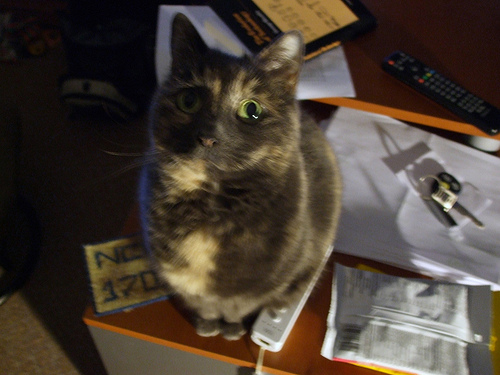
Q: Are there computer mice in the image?
A: No, there are no computer mice.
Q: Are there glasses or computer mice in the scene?
A: No, there are no computer mice or glasses.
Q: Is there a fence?
A: No, there are no fences.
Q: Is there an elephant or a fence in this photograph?
A: No, there are no fences or elephants.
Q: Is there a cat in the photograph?
A: Yes, there is a cat.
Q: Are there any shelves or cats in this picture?
A: Yes, there is a cat.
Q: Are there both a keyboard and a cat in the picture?
A: No, there is a cat but no keyboards.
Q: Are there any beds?
A: No, there are no beds.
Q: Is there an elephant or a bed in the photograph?
A: No, there are no beds or elephants.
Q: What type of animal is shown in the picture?
A: The animal is a cat.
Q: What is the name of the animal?
A: The animal is a cat.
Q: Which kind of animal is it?
A: The animal is a cat.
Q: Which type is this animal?
A: This is a cat.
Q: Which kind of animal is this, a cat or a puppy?
A: This is a cat.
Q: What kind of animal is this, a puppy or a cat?
A: This is a cat.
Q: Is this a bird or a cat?
A: This is a cat.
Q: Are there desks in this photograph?
A: Yes, there is a desk.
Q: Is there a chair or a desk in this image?
A: Yes, there is a desk.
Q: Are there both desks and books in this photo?
A: No, there is a desk but no books.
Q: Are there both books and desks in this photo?
A: No, there is a desk but no books.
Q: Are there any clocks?
A: No, there are no clocks.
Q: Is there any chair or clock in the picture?
A: No, there are no clocks or chairs.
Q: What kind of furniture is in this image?
A: The furniture is a desk.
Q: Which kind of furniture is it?
A: The piece of furniture is a desk.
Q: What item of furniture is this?
A: That is a desk.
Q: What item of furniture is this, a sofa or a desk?
A: That is a desk.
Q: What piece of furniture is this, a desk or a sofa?
A: That is a desk.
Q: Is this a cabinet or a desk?
A: This is a desk.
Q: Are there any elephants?
A: No, there are no elephants.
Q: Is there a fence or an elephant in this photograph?
A: No, there are no elephants or fences.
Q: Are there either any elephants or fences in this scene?
A: No, there are no elephants or fences.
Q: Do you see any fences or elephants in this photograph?
A: No, there are no elephants or fences.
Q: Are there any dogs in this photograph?
A: No, there are no dogs.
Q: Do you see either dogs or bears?
A: No, there are no dogs or bears.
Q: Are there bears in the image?
A: No, there are no bears.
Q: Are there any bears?
A: No, there are no bears.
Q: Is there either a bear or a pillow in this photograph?
A: No, there are no bears or pillows.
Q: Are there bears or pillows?
A: No, there are no bears or pillows.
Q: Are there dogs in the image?
A: No, there are no dogs.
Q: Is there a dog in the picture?
A: No, there are no dogs.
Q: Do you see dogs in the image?
A: No, there are no dogs.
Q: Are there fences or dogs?
A: No, there are no dogs or fences.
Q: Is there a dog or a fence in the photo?
A: No, there are no dogs or fences.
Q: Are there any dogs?
A: No, there are no dogs.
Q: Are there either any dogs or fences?
A: No, there are no dogs or fences.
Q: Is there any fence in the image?
A: No, there are no fences.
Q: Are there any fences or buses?
A: No, there are no fences or buses.